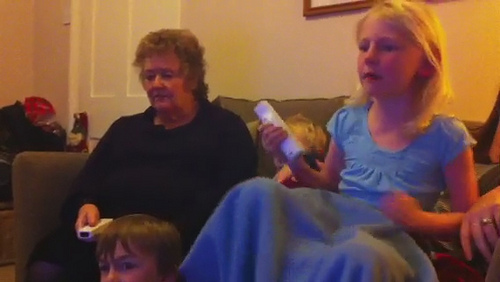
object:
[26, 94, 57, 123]
flower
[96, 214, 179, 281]
boy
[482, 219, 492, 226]
wedding band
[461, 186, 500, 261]
hand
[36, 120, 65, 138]
bag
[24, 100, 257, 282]
shirt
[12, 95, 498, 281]
couch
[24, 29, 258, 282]
grandma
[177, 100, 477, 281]
shirt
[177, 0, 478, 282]
girl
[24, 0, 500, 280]
people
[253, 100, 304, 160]
controller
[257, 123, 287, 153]
hand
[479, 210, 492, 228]
ring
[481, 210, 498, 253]
finger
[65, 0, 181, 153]
door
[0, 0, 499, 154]
wall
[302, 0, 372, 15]
picture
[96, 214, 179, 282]
child's head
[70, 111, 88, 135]
door knob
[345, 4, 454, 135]
hair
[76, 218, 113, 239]
controller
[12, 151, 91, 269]
couch arm